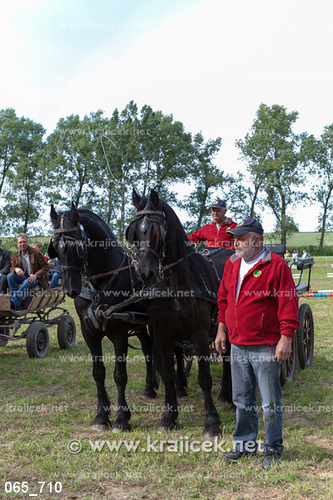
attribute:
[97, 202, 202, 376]
horse — brown, carriage, blinder, black, grass, wagon, drawn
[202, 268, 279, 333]
jacket — red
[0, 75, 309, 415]
people — watching, group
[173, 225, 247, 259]
rail — hand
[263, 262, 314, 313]
coat — red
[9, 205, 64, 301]
man — sitting, wearing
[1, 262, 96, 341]
wagon — wooden, brown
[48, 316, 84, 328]
tire — black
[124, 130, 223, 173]
leave — green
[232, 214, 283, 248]
hat — blue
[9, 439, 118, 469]
grass — green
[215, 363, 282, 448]
jean — blue, denim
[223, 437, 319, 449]
shoe — black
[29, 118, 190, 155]
tree — green